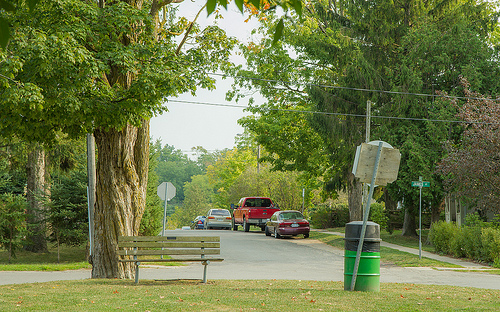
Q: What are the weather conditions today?
A: It is cloudy.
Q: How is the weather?
A: It is cloudy.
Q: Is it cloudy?
A: Yes, it is cloudy.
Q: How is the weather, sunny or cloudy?
A: It is cloudy.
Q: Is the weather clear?
A: No, it is cloudy.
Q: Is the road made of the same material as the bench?
A: No, the road is made of cement and the bench is made of wood.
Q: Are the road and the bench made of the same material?
A: No, the road is made of cement and the bench is made of wood.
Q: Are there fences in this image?
A: No, there are no fences.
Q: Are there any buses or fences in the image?
A: No, there are no fences or buses.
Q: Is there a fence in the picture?
A: No, there are no fences.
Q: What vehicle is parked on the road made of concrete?
A: The vehicle is a car.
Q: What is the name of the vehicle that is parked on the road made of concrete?
A: The vehicle is a car.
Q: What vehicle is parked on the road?
A: The vehicle is a car.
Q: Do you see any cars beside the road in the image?
A: Yes, there is a car beside the road.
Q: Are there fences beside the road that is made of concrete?
A: No, there is a car beside the road.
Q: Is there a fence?
A: No, there are no fences.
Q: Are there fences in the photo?
A: No, there are no fences.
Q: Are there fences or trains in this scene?
A: No, there are no fences or trains.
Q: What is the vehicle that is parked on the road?
A: The vehicle is a car.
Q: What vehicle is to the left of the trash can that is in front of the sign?
A: The vehicle is a car.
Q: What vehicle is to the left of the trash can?
A: The vehicle is a car.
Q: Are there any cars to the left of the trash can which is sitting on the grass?
A: Yes, there is a car to the left of the garbage can.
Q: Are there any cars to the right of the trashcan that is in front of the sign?
A: No, the car is to the left of the trashcan.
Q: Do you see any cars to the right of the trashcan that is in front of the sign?
A: No, the car is to the left of the trashcan.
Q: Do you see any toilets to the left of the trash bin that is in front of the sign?
A: No, there is a car to the left of the trash can.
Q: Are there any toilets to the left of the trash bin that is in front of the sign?
A: No, there is a car to the left of the trash can.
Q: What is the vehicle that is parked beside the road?
A: The vehicle is a car.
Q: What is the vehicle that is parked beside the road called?
A: The vehicle is a car.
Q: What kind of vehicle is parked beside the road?
A: The vehicle is a car.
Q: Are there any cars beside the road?
A: Yes, there is a car beside the road.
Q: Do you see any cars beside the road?
A: Yes, there is a car beside the road.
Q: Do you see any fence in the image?
A: No, there are no fences.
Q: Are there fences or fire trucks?
A: No, there are no fences or fire trucks.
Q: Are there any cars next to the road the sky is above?
A: Yes, there is a car next to the road.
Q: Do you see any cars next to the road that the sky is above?
A: Yes, there is a car next to the road.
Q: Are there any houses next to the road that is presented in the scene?
A: No, there is a car next to the road.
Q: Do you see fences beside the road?
A: No, there is a car beside the road.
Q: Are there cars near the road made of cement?
A: Yes, there is a car near the road.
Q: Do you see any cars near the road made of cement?
A: Yes, there is a car near the road.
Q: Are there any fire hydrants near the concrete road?
A: No, there is a car near the road.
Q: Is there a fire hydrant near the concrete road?
A: No, there is a car near the road.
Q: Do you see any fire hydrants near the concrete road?
A: No, there is a car near the road.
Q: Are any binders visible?
A: No, there are no binders.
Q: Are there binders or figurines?
A: No, there are no binders or figurines.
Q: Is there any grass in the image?
A: Yes, there is grass.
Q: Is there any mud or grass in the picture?
A: Yes, there is grass.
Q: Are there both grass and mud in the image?
A: No, there is grass but no mud.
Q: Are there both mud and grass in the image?
A: No, there is grass but no mud.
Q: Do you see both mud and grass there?
A: No, there is grass but no mud.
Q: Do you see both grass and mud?
A: No, there is grass but no mud.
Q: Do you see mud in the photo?
A: No, there is no mud.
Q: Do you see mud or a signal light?
A: No, there are no mud or traffic lights.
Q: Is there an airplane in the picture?
A: No, there are no airplanes.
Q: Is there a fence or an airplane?
A: No, there are no airplanes or fences.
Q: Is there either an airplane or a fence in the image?
A: No, there are no airplanes or fences.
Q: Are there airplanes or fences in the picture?
A: No, there are no airplanes or fences.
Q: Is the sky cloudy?
A: Yes, the sky is cloudy.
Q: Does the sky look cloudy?
A: Yes, the sky is cloudy.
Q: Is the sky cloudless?
A: No, the sky is cloudy.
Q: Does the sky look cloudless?
A: No, the sky is cloudy.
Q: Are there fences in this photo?
A: No, there are no fences.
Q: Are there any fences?
A: No, there are no fences.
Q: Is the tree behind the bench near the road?
A: Yes, the tree is behind the bench.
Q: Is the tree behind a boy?
A: No, the tree is behind the bench.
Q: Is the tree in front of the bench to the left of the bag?
A: No, the tree is behind the bench.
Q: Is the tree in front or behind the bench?
A: The tree is behind the bench.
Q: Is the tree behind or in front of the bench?
A: The tree is behind the bench.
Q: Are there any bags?
A: Yes, there is a bag.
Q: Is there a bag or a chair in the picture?
A: Yes, there is a bag.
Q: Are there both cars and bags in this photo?
A: Yes, there are both a bag and a car.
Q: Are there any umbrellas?
A: No, there are no umbrellas.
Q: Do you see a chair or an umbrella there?
A: No, there are no umbrellas or chairs.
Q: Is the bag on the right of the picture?
A: Yes, the bag is on the right of the image.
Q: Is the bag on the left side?
A: No, the bag is on the right of the image.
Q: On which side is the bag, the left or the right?
A: The bag is on the right of the image.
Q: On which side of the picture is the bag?
A: The bag is on the right of the image.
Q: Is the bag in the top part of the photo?
A: No, the bag is in the bottom of the image.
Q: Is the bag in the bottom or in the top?
A: The bag is in the bottom of the image.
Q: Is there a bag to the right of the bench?
A: Yes, there is a bag to the right of the bench.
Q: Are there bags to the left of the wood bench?
A: No, the bag is to the right of the bench.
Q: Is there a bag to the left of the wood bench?
A: No, the bag is to the right of the bench.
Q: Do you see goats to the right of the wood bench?
A: No, there is a bag to the right of the bench.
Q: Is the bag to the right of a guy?
A: No, the bag is to the right of the bench.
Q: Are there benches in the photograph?
A: Yes, there is a bench.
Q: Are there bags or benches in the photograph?
A: Yes, there is a bench.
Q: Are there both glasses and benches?
A: No, there is a bench but no glasses.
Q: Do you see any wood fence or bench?
A: Yes, there is a wood bench.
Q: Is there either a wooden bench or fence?
A: Yes, there is a wood bench.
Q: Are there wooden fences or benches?
A: Yes, there is a wood bench.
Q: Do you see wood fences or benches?
A: Yes, there is a wood bench.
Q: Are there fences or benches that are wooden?
A: Yes, the bench is wooden.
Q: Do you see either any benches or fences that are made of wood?
A: Yes, the bench is made of wood.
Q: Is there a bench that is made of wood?
A: Yes, there is a bench that is made of wood.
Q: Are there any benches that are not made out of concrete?
A: Yes, there is a bench that is made of wood.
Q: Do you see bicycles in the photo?
A: No, there are no bicycles.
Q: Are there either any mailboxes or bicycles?
A: No, there are no bicycles or mailboxes.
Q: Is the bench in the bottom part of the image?
A: Yes, the bench is in the bottom of the image.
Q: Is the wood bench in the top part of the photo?
A: No, the bench is in the bottom of the image.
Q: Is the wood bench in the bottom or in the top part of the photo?
A: The bench is in the bottom of the image.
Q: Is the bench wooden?
A: Yes, the bench is wooden.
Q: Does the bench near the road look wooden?
A: Yes, the bench is wooden.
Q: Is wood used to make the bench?
A: Yes, the bench is made of wood.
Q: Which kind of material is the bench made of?
A: The bench is made of wood.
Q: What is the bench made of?
A: The bench is made of wood.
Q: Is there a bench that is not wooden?
A: No, there is a bench but it is wooden.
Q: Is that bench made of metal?
A: No, the bench is made of wood.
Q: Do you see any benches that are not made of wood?
A: No, there is a bench but it is made of wood.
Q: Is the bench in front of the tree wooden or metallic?
A: The bench is wooden.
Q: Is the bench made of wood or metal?
A: The bench is made of wood.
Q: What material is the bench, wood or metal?
A: The bench is made of wood.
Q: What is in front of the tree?
A: The bench is in front of the tree.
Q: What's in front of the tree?
A: The bench is in front of the tree.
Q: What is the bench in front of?
A: The bench is in front of the tree.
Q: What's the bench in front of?
A: The bench is in front of the tree.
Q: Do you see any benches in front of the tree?
A: Yes, there is a bench in front of the tree.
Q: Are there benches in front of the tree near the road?
A: Yes, there is a bench in front of the tree.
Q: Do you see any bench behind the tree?
A: No, the bench is in front of the tree.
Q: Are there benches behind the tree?
A: No, the bench is in front of the tree.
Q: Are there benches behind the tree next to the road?
A: No, the bench is in front of the tree.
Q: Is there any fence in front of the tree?
A: No, there is a bench in front of the tree.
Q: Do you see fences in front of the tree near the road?
A: No, there is a bench in front of the tree.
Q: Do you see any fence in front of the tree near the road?
A: No, there is a bench in front of the tree.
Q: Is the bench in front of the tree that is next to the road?
A: Yes, the bench is in front of the tree.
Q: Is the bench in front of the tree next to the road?
A: Yes, the bench is in front of the tree.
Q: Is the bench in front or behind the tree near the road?
A: The bench is in front of the tree.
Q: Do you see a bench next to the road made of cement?
A: Yes, there is a bench next to the road.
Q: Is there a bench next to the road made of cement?
A: Yes, there is a bench next to the road.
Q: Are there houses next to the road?
A: No, there is a bench next to the road.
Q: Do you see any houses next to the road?
A: No, there is a bench next to the road.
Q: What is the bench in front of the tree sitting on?
A: The bench is sitting on the grass.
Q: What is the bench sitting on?
A: The bench is sitting on the grass.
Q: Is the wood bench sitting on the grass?
A: Yes, the bench is sitting on the grass.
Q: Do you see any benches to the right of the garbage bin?
A: No, the bench is to the left of the garbage bin.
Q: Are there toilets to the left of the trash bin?
A: No, there is a bench to the left of the trash bin.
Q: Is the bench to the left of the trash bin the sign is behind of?
A: Yes, the bench is to the left of the trashcan.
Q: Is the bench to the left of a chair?
A: No, the bench is to the left of the trashcan.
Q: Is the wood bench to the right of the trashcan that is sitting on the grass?
A: No, the bench is to the left of the garbage bin.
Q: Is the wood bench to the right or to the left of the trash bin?
A: The bench is to the left of the trash bin.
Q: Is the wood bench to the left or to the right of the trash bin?
A: The bench is to the left of the trash bin.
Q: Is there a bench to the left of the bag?
A: Yes, there is a bench to the left of the bag.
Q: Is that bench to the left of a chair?
A: No, the bench is to the left of the bag.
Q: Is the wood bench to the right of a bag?
A: No, the bench is to the left of a bag.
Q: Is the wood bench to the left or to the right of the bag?
A: The bench is to the left of the bag.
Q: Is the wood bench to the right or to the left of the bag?
A: The bench is to the left of the bag.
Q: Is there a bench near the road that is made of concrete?
A: Yes, there is a bench near the road.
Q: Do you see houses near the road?
A: No, there is a bench near the road.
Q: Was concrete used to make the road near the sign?
A: Yes, the road is made of concrete.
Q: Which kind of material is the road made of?
A: The road is made of cement.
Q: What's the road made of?
A: The road is made of concrete.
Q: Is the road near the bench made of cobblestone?
A: No, the road is made of cement.